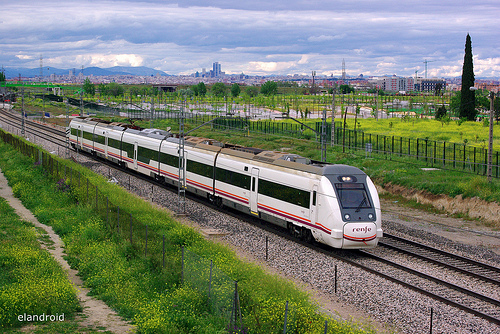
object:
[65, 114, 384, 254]
train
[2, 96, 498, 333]
fence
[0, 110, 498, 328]
track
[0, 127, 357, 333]
plant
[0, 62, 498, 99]
buildings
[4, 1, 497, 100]
cloud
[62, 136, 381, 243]
stripe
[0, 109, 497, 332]
gravel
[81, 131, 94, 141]
window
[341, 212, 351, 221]
headlight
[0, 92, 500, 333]
ground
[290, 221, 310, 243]
wheel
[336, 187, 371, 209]
windshield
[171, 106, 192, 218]
pole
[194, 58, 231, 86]
skyscraper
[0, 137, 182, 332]
grass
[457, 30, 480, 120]
tree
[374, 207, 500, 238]
line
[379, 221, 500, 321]
path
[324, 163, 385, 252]
front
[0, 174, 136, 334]
path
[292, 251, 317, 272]
pebbles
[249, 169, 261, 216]
door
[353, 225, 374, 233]
word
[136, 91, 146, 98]
light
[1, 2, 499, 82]
sky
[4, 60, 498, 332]
spain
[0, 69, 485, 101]
horizon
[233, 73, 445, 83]
city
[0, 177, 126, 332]
trail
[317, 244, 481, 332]
rocks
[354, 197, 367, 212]
wipers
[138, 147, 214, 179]
windows